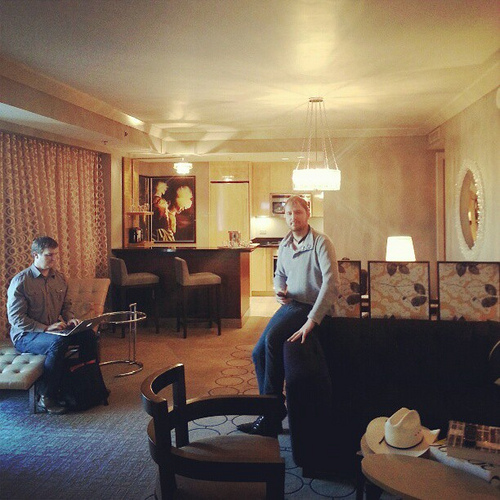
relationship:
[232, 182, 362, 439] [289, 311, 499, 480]
man on couch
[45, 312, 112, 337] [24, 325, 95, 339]
laptop on lap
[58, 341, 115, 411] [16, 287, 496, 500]
backpack on floor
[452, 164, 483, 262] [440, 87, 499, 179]
mirror on wall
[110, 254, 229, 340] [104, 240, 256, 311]
chairs under counter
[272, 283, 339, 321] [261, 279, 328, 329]
phone in hand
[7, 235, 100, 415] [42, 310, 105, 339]
man on laptop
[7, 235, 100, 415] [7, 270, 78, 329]
man wearing shirt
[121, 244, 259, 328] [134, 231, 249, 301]
stool next to bar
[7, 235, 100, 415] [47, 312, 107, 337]
man using laptop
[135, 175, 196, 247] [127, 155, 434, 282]
picture on wall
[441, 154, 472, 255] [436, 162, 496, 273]
mirror on wall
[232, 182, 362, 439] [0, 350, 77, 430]
man sitting on chair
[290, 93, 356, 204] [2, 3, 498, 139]
lights are hanging from ceiling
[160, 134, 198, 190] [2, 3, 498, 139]
lights are hanging from ceiling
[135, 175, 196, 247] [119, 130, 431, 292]
picture hanging in wall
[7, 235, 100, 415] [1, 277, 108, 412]
man sitting on chair